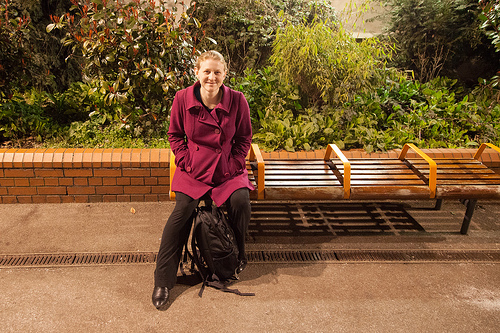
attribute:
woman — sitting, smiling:
[133, 34, 263, 307]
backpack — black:
[189, 205, 252, 300]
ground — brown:
[3, 201, 497, 332]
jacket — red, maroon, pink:
[166, 91, 259, 202]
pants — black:
[156, 189, 251, 280]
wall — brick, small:
[4, 151, 498, 203]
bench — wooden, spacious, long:
[166, 144, 499, 207]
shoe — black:
[150, 282, 170, 308]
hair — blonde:
[193, 45, 234, 71]